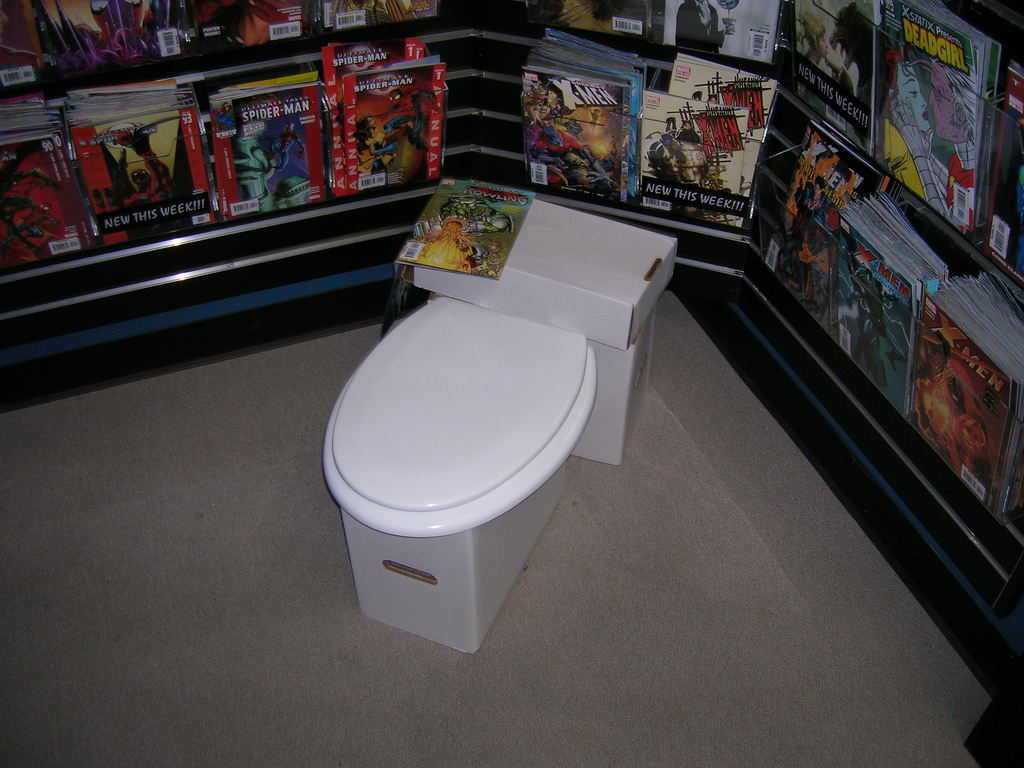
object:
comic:
[520, 27, 646, 203]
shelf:
[0, 0, 1022, 768]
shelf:
[0, 0, 480, 418]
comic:
[321, 38, 445, 198]